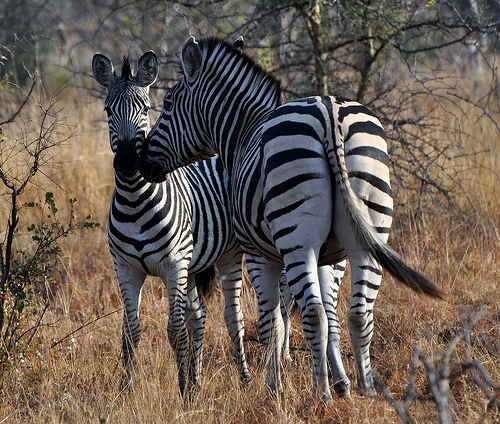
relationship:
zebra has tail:
[149, 35, 433, 388] [322, 110, 448, 311]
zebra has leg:
[149, 35, 433, 388] [279, 270, 351, 404]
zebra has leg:
[149, 35, 433, 388] [349, 261, 378, 388]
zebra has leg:
[149, 35, 433, 388] [210, 244, 239, 361]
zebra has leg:
[149, 35, 433, 388] [265, 243, 308, 370]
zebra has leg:
[149, 35, 433, 388] [110, 274, 154, 414]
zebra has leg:
[149, 35, 433, 388] [186, 276, 219, 410]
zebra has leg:
[149, 35, 433, 388] [171, 285, 197, 386]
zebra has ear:
[149, 35, 433, 388] [178, 37, 211, 97]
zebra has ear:
[149, 35, 433, 388] [140, 43, 172, 96]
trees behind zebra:
[245, 14, 455, 93] [149, 35, 433, 388]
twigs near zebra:
[359, 301, 498, 421] [149, 35, 433, 388]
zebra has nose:
[149, 35, 433, 388] [95, 142, 181, 199]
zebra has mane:
[149, 35, 433, 388] [188, 34, 321, 113]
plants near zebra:
[1, 167, 83, 371] [149, 35, 433, 388]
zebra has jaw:
[149, 35, 433, 388] [171, 119, 208, 182]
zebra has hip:
[149, 35, 433, 388] [247, 109, 322, 186]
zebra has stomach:
[149, 35, 433, 388] [237, 211, 274, 282]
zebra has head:
[149, 35, 433, 388] [124, 50, 248, 183]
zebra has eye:
[149, 35, 433, 388] [151, 99, 188, 122]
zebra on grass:
[149, 35, 433, 388] [14, 338, 150, 423]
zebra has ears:
[88, 52, 274, 407] [95, 54, 164, 104]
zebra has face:
[88, 52, 274, 407] [105, 53, 152, 187]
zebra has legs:
[149, 35, 433, 388] [223, 250, 397, 397]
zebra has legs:
[88, 52, 274, 407] [117, 258, 271, 420]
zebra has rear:
[149, 35, 433, 388] [259, 85, 393, 351]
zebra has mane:
[88, 52, 274, 407] [113, 43, 139, 96]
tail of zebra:
[322, 110, 448, 311] [149, 35, 433, 388]